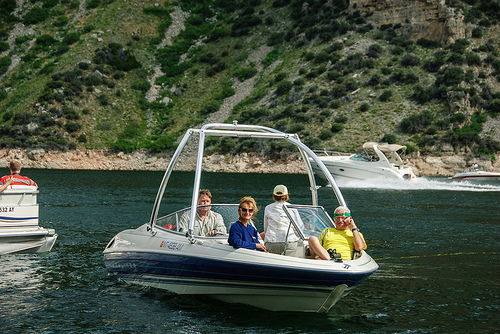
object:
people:
[263, 184, 305, 259]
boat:
[102, 119, 380, 313]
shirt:
[318, 227, 367, 261]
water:
[0, 167, 499, 334]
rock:
[117, 151, 129, 160]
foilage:
[333, 212, 351, 218]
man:
[308, 205, 367, 259]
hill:
[1, 0, 500, 173]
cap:
[273, 184, 289, 197]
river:
[0, 167, 500, 334]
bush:
[358, 102, 370, 112]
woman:
[227, 196, 268, 254]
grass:
[108, 76, 185, 154]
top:
[227, 220, 261, 249]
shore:
[447, 162, 500, 182]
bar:
[148, 203, 336, 239]